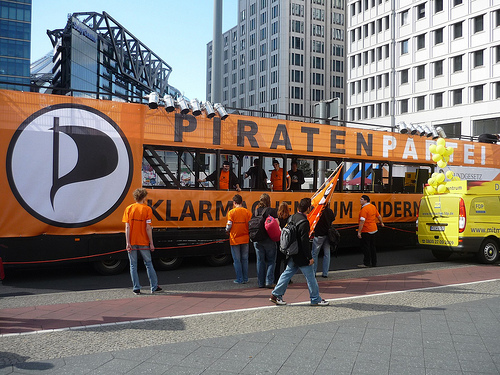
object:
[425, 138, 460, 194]
balloons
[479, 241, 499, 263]
tire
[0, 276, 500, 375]
walkway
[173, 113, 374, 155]
letters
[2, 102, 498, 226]
sign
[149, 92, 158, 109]
light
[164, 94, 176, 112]
light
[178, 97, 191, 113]
light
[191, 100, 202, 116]
light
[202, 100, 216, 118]
light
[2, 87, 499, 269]
bus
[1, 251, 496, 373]
road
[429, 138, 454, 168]
balloons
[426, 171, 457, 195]
balloons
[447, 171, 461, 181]
balloons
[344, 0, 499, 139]
office buildings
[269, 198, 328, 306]
guy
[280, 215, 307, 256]
backpack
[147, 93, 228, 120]
silver lights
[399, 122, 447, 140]
silver lights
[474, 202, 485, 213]
blue letters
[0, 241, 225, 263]
rope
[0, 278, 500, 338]
line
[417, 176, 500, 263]
van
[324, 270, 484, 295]
concrete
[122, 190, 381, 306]
guys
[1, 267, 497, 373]
shadow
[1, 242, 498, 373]
ground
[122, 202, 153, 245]
orange t-shirt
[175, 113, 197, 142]
word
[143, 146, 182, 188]
staircase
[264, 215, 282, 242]
bag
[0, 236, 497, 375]
street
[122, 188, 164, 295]
man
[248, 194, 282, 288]
person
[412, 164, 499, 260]
car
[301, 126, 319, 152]
letter t